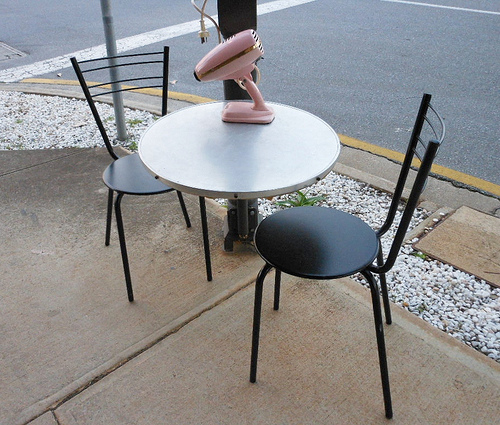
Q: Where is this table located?
A: On sidewalk.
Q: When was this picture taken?
A: Daytime.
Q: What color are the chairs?
A: Black.